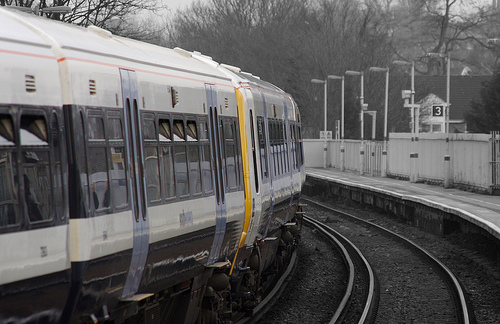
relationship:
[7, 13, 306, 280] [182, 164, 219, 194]
train for passengers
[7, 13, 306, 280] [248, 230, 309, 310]
train on a curve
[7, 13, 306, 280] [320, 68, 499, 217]
train going past train stop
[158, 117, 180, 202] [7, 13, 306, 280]
window on train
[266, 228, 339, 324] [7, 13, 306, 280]
ground next to train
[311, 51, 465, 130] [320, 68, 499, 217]
lamps line train stop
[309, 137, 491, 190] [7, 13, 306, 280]
fence along side train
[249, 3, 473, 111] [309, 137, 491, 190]
trees beyond fence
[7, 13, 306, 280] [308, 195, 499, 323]
train on railway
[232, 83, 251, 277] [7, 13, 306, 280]
stripe on train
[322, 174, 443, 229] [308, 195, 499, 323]
ledge by railway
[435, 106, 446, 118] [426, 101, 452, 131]
number on sign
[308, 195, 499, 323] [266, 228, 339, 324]
railway on ground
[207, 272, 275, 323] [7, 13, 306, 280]
wheels of train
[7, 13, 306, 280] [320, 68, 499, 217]
train at a train stop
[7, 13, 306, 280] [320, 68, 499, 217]
train at train stop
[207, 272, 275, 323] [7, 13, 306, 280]
wheels on train